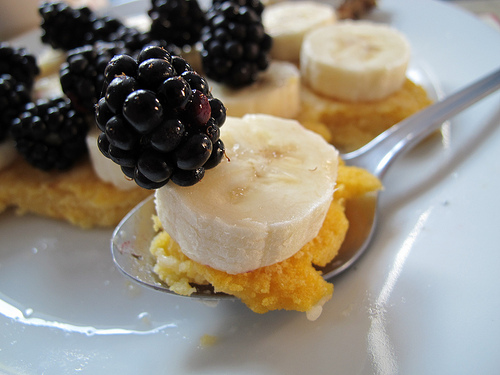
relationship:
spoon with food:
[102, 59, 500, 302] [110, 50, 498, 302]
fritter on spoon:
[157, 233, 355, 314] [110, 50, 498, 302]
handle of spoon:
[350, 67, 498, 195] [110, 50, 498, 302]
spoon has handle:
[110, 50, 498, 302] [350, 67, 498, 195]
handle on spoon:
[350, 67, 498, 195] [110, 50, 498, 302]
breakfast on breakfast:
[5, 3, 440, 294] [0, 0, 461, 325]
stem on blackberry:
[220, 147, 232, 164] [96, 50, 224, 188]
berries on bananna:
[96, 50, 224, 188] [155, 112, 345, 276]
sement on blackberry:
[192, 95, 214, 121] [96, 50, 224, 188]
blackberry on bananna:
[96, 50, 224, 188] [155, 112, 345, 276]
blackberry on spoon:
[96, 50, 224, 188] [110, 50, 498, 302]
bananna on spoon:
[155, 112, 345, 276] [110, 50, 498, 302]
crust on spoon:
[140, 162, 386, 325] [110, 50, 498, 302]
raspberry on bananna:
[96, 50, 224, 188] [155, 112, 345, 276]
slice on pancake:
[157, 109, 342, 272] [140, 162, 386, 325]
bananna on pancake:
[155, 112, 345, 276] [140, 162, 386, 325]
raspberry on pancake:
[96, 50, 224, 188] [140, 162, 386, 325]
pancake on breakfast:
[4, 10, 448, 230] [0, 0, 461, 325]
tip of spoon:
[103, 211, 159, 301] [110, 50, 498, 302]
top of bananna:
[166, 116, 339, 223] [155, 112, 345, 276]